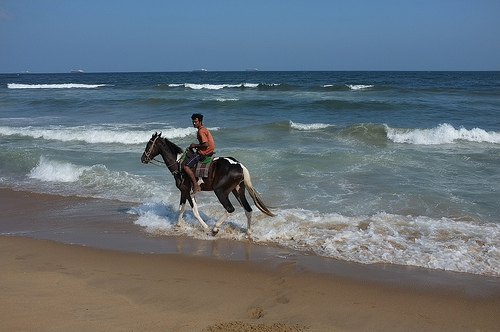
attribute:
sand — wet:
[3, 186, 497, 330]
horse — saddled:
[128, 122, 261, 243]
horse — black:
[140, 132, 270, 244]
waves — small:
[252, 36, 499, 231]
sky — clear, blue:
[1, 3, 497, 76]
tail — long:
[239, 162, 277, 215]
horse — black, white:
[136, 127, 283, 240]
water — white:
[26, 152, 499, 274]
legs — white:
[168, 197, 260, 235]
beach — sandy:
[263, 211, 442, 329]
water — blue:
[327, 89, 478, 149]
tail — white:
[244, 170, 274, 220]